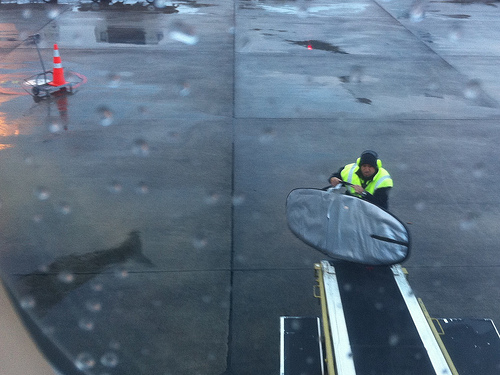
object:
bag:
[283, 181, 412, 267]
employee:
[328, 149, 394, 208]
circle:
[59, 266, 75, 283]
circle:
[68, 350, 100, 374]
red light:
[308, 45, 313, 49]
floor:
[0, 0, 500, 375]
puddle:
[285, 39, 349, 56]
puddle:
[0, 0, 206, 49]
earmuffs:
[358, 154, 379, 171]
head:
[357, 149, 378, 178]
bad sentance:
[131, 135, 153, 156]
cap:
[358, 150, 378, 172]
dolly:
[22, 71, 73, 103]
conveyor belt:
[309, 260, 461, 375]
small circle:
[104, 181, 122, 194]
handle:
[23, 35, 51, 85]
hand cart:
[23, 31, 72, 95]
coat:
[339, 157, 394, 199]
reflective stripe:
[345, 164, 355, 183]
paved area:
[0, 0, 500, 375]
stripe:
[53, 48, 61, 58]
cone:
[45, 42, 70, 87]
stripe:
[52, 56, 62, 64]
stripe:
[53, 42, 59, 50]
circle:
[284, 177, 415, 274]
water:
[0, 0, 497, 375]